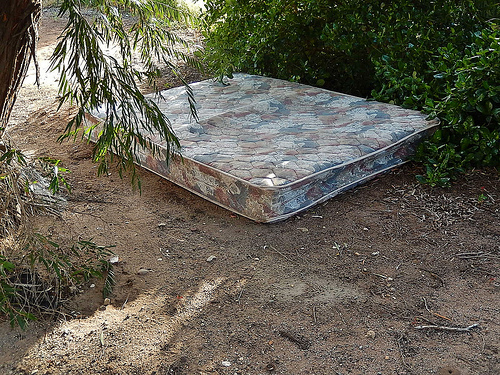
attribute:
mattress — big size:
[94, 74, 421, 253]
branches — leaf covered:
[51, 9, 202, 202]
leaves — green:
[433, 40, 485, 105]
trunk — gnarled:
[7, 10, 106, 143]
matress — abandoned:
[72, 29, 474, 271]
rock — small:
[131, 265, 154, 277]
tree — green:
[284, 2, 497, 99]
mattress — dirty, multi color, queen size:
[85, 70, 440, 226]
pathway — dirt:
[0, 2, 499, 372]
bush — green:
[191, 11, 498, 183]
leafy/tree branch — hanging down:
[45, 2, 253, 183]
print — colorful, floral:
[112, 82, 466, 201]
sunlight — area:
[42, 30, 194, 85]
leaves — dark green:
[431, 9, 499, 154]